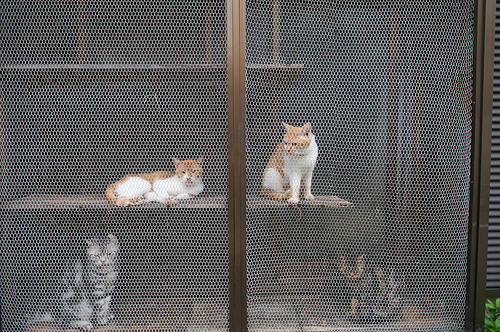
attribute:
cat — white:
[99, 165, 195, 214]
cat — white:
[263, 121, 339, 211]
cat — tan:
[104, 149, 221, 211]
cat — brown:
[313, 240, 424, 331]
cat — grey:
[29, 217, 139, 331]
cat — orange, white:
[263, 111, 333, 227]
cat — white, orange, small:
[110, 150, 219, 229]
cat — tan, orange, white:
[252, 114, 328, 209]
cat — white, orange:
[107, 143, 199, 217]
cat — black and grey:
[54, 234, 124, 332]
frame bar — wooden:
[217, 57, 256, 318]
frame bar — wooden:
[439, 159, 494, 332]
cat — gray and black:
[31, 224, 130, 332]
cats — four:
[46, 121, 426, 332]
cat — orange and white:
[104, 153, 209, 233]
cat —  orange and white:
[94, 107, 346, 244]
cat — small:
[266, 119, 322, 216]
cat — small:
[32, 240, 141, 332]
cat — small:
[330, 245, 415, 332]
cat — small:
[60, 241, 126, 322]